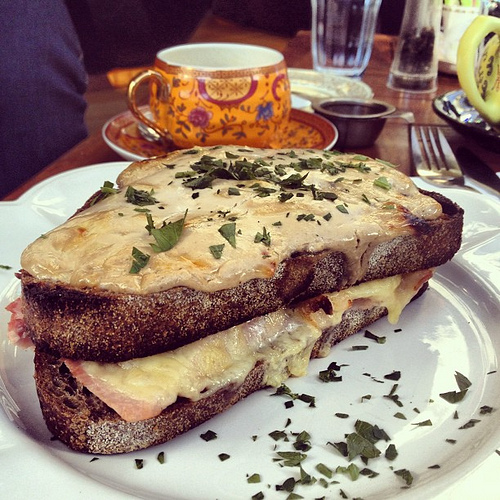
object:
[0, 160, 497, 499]
plate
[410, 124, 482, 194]
fork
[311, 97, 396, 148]
container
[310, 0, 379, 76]
glass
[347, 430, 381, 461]
garnish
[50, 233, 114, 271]
cream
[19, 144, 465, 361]
bread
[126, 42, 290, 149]
cup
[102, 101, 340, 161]
saucer